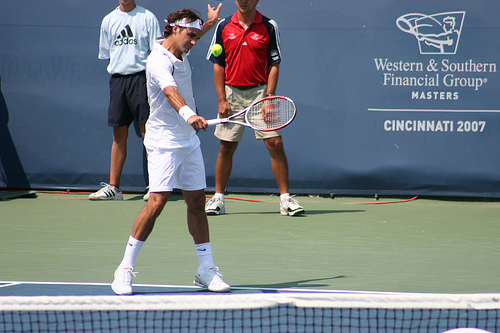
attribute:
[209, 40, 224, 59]
tennis ball — in mid air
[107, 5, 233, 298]
tennis player — serving the ball, in a white outfit, with a white headband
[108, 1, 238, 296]
male/tennis player — serving, dressed in white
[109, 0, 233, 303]
tennis pro — serving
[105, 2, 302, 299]
man — holding a tennis racket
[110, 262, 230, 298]
white shoes — tied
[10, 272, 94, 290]
white line — on court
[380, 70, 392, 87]
white letter — on wall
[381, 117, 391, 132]
white letter — on wall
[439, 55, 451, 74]
white letter — on wall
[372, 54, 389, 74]
white letter — on wall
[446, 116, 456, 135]
white letter — on wall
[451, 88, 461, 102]
white letter — on wall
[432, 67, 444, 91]
white letter — on wall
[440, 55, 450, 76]
white letter — on wall